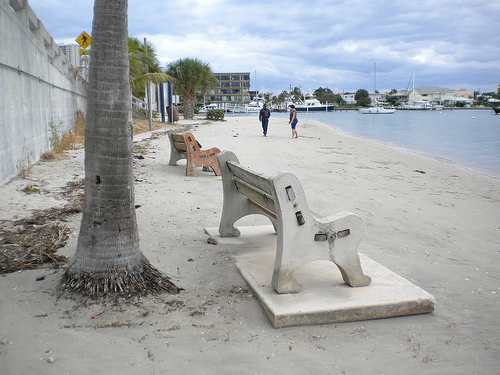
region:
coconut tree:
[60, 3, 159, 296]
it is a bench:
[217, 146, 413, 316]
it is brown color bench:
[165, 127, 223, 173]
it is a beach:
[242, 50, 493, 146]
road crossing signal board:
[75, 30, 90, 50]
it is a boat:
[356, 101, 396, 111]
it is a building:
[221, 70, 257, 96]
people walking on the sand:
[256, 100, 301, 145]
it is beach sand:
[375, 150, 442, 246]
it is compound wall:
[7, 0, 57, 182]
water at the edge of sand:
[381, 136, 447, 178]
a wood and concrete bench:
[199, 140, 391, 313]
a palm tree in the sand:
[58, 110, 180, 317]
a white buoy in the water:
[468, 112, 477, 126]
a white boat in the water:
[356, 101, 399, 120]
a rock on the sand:
[42, 351, 65, 370]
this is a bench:
[183, 124, 401, 322]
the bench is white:
[203, 136, 382, 339]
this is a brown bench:
[148, 90, 228, 181]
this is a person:
[282, 97, 319, 159]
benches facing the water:
[145, 82, 489, 363]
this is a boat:
[280, 84, 331, 118]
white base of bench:
[197, 202, 419, 329]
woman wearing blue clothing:
[283, 102, 305, 130]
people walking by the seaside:
[249, 93, 301, 138]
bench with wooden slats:
[213, 151, 436, 324]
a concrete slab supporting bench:
[205, 223, 436, 332]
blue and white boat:
[283, 96, 336, 113]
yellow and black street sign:
[75, 32, 91, 53]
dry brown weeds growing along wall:
[45, 108, 85, 158]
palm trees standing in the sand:
[166, 59, 236, 129]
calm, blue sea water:
[396, 112, 481, 147]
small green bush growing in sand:
[205, 108, 225, 123]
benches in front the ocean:
[168, 117, 480, 338]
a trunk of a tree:
[71, 2, 156, 294]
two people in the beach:
[249, 101, 312, 142]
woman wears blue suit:
[284, 99, 302, 140]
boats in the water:
[350, 55, 435, 117]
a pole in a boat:
[408, 64, 420, 104]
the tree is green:
[164, 54, 219, 121]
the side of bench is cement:
[265, 169, 374, 296]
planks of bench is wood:
[225, 160, 308, 225]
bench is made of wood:
[164, 127, 223, 179]